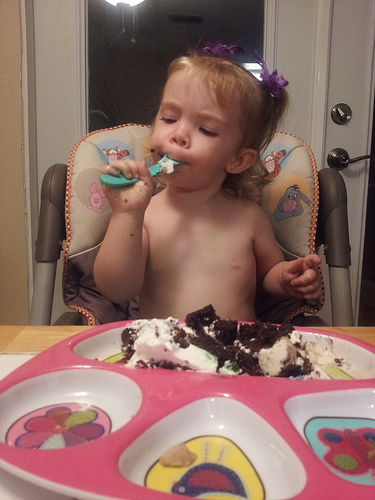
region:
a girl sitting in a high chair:
[84, 39, 374, 399]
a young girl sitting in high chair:
[108, 51, 336, 303]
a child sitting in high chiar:
[151, 84, 372, 364]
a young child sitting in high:
[46, 51, 365, 381]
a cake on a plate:
[109, 309, 371, 473]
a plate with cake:
[118, 271, 364, 447]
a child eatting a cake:
[97, 36, 372, 376]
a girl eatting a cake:
[142, 43, 373, 386]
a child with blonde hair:
[158, 36, 291, 249]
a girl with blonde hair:
[206, 45, 279, 140]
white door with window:
[26, 4, 372, 323]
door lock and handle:
[325, 101, 371, 169]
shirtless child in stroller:
[32, 39, 348, 322]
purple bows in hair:
[174, 45, 288, 137]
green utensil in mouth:
[102, 155, 180, 188]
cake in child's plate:
[0, 305, 372, 497]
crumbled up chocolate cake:
[129, 303, 311, 375]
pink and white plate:
[0, 317, 374, 497]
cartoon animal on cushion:
[271, 180, 310, 223]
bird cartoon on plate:
[169, 438, 248, 496]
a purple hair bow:
[254, 55, 289, 101]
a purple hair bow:
[200, 38, 248, 58]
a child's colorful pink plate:
[1, 319, 374, 499]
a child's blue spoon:
[99, 155, 186, 189]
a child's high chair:
[16, 120, 356, 323]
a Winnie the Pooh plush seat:
[65, 122, 326, 321]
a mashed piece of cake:
[121, 306, 309, 377]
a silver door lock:
[330, 100, 351, 125]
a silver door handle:
[327, 147, 374, 171]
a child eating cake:
[90, 39, 321, 321]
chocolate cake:
[158, 325, 268, 372]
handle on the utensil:
[103, 173, 118, 190]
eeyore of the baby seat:
[277, 189, 310, 221]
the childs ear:
[232, 151, 256, 174]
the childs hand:
[286, 249, 325, 298]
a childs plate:
[11, 376, 364, 481]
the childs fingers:
[297, 278, 319, 299]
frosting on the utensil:
[163, 159, 172, 171]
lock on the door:
[331, 108, 351, 126]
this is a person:
[91, 39, 323, 324]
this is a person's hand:
[92, 158, 153, 300]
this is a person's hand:
[242, 200, 320, 304]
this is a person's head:
[146, 42, 290, 190]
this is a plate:
[2, 305, 366, 495]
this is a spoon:
[96, 153, 184, 187]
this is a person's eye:
[193, 118, 226, 138]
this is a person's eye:
[157, 99, 177, 127]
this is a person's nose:
[170, 128, 194, 146]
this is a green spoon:
[101, 148, 185, 194]